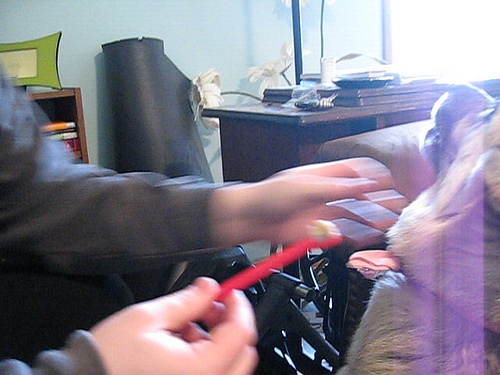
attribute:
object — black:
[235, 249, 337, 291]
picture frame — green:
[4, 26, 71, 88]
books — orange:
[53, 125, 88, 149]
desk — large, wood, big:
[204, 91, 331, 135]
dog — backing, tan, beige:
[422, 102, 475, 351]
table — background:
[214, 125, 311, 157]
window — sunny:
[357, 1, 476, 71]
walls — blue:
[170, 7, 219, 33]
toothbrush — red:
[306, 211, 347, 269]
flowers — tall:
[233, 46, 311, 110]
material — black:
[271, 86, 293, 100]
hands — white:
[148, 185, 322, 337]